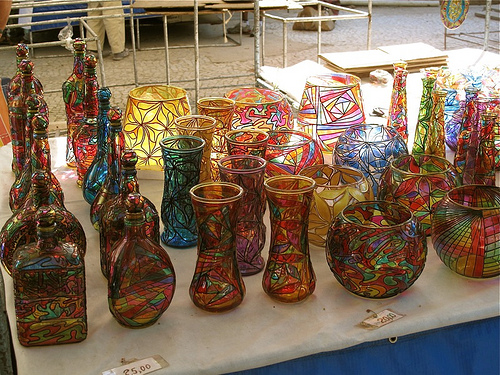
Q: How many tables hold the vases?
A: One.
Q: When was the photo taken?
A: Daytime.